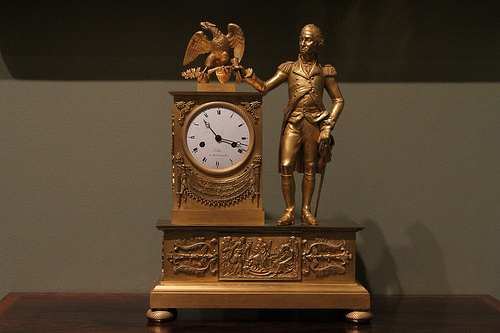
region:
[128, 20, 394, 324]
A gold colored decorative clock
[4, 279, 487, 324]
A brown wooden table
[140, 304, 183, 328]
Foot pads holding up a decorative clock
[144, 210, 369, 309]
Designs etched onto the base of a clock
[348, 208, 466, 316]
The shadow of a decorative clock on the wall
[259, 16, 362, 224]
A small image of George Washington standing on the base of a clock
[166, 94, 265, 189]
A white clock face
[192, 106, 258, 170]
Black hands on a clock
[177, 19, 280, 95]
An eagle perched on the top of a decorative clock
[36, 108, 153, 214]
A grey wall in the background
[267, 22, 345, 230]
Golden statue of a man with a cane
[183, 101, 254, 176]
White and black clock face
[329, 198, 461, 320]
Shadows of the clock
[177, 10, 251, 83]
Golden winged creature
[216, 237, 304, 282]
Small golden image on base of statue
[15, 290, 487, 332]
Dark wooden table under statue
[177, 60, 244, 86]
Golden branch in creature's claws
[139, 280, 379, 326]
Base of golden statue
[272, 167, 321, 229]
Socks and shoes on golden statue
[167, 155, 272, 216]
Golden decorations around clock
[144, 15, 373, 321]
small gold clock statue on a table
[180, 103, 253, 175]
clock with white face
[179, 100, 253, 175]
roman numerals on clock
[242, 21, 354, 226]
statue of a soldier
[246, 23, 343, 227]
small gold statue of a soldier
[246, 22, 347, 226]
gold soldier holding a sword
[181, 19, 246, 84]
gold statue of a bird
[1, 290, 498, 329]
back of wooden table top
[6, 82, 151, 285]
gray wall behind the clock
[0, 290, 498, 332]
brown wooden table with gold clock on top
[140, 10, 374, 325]
the clock is gold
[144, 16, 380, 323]
the clock is old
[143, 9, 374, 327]
the clock is tacky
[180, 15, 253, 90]
the eagle is on the clock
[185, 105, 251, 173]
the clock face is white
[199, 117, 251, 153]
the clock has black hands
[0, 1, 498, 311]
the wall is tan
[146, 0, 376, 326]
the clock is patriotic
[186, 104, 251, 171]
the numbers on the clock are roman numerals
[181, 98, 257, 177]
the numbers are black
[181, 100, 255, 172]
Face of the clock is white.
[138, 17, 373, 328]
The clock is gold.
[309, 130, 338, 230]
Man has a sword.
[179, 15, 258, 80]
Bird above the clock.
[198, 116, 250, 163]
Hands of the clock are black.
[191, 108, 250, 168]
Numbers on the clock are black.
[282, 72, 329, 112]
Buttons on the jacket.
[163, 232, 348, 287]
Design on the base.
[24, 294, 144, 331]
The table is wooden.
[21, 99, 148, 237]
The wall is white.